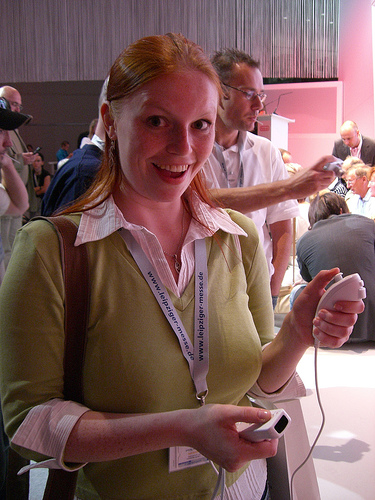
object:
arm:
[209, 178, 302, 212]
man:
[56, 140, 73, 162]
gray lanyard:
[212, 139, 245, 191]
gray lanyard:
[115, 225, 211, 399]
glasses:
[220, 80, 268, 102]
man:
[338, 154, 375, 222]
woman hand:
[290, 264, 366, 351]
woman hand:
[187, 400, 278, 472]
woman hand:
[35, 185, 40, 192]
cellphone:
[32, 146, 41, 154]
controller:
[311, 271, 369, 353]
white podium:
[256, 110, 295, 154]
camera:
[321, 154, 346, 179]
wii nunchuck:
[212, 270, 367, 500]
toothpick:
[250, 116, 264, 128]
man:
[39, 69, 112, 219]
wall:
[337, 1, 375, 127]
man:
[295, 188, 375, 353]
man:
[30, 149, 51, 197]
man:
[0, 85, 35, 250]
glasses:
[342, 172, 362, 184]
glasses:
[6, 99, 23, 111]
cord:
[288, 338, 325, 498]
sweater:
[0, 184, 275, 500]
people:
[0, 30, 365, 500]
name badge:
[166, 441, 209, 474]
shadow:
[304, 437, 371, 465]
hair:
[211, 46, 263, 95]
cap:
[0, 95, 34, 131]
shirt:
[197, 127, 302, 285]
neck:
[210, 112, 242, 149]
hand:
[299, 152, 335, 199]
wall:
[270, 85, 338, 156]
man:
[330, 118, 375, 167]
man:
[197, 47, 298, 314]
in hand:
[283, 264, 366, 352]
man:
[0, 95, 31, 291]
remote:
[232, 406, 292, 444]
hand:
[283, 266, 365, 348]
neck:
[108, 167, 193, 217]